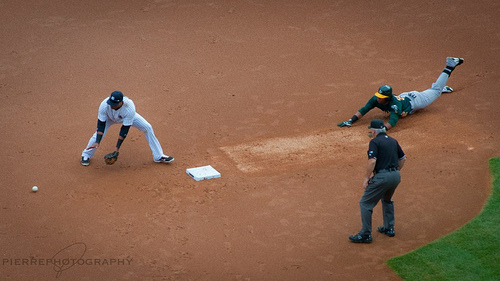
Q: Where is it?
A: This is at the field.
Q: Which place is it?
A: It is a field.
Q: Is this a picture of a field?
A: Yes, it is showing a field.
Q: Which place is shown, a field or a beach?
A: It is a field.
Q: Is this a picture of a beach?
A: No, the picture is showing a field.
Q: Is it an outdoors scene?
A: Yes, it is outdoors.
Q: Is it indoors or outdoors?
A: It is outdoors.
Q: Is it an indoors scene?
A: No, it is outdoors.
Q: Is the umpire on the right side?
A: Yes, the umpire is on the right of the image.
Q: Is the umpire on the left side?
A: No, the umpire is on the right of the image.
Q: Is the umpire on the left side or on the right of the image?
A: The umpire is on the right of the image.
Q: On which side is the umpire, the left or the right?
A: The umpire is on the right of the image.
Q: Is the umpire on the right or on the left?
A: The umpire is on the right of the image.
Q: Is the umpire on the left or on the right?
A: The umpire is on the right of the image.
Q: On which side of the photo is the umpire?
A: The umpire is on the right of the image.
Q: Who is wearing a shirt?
A: The umpire is wearing a shirt.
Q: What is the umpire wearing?
A: The umpire is wearing a shirt.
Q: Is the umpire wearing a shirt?
A: Yes, the umpire is wearing a shirt.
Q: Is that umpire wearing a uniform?
A: No, the umpire is wearing a shirt.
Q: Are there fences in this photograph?
A: No, there are no fences.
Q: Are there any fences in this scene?
A: No, there are no fences.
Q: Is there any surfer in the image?
A: No, there are no surfers.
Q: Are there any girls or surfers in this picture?
A: No, there are no surfers or girls.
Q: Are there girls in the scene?
A: No, there are no girls.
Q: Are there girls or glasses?
A: No, there are no girls or glasses.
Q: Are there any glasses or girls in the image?
A: No, there are no girls or glasses.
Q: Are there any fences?
A: No, there are no fences.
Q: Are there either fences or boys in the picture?
A: No, there are no fences or boys.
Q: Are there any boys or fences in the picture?
A: No, there are no fences or boys.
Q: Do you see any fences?
A: No, there are no fences.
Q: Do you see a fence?
A: No, there are no fences.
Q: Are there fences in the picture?
A: No, there are no fences.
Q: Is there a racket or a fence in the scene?
A: No, there are no fences or rackets.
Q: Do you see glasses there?
A: No, there are no glasses.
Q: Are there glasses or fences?
A: No, there are no glasses or fences.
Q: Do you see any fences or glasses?
A: No, there are no glasses or fences.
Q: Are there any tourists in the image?
A: No, there are no tourists.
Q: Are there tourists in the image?
A: No, there are no tourists.